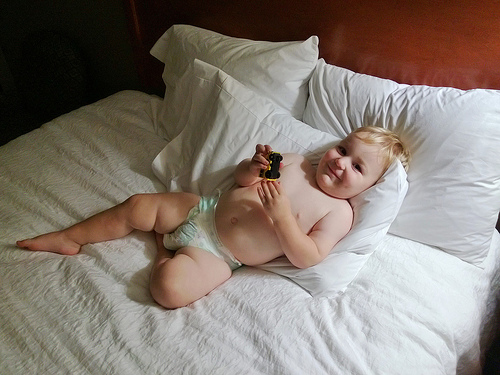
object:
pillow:
[302, 58, 500, 270]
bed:
[2, 88, 500, 374]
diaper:
[162, 197, 244, 271]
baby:
[17, 125, 412, 309]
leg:
[67, 191, 200, 246]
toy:
[259, 152, 282, 182]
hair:
[353, 125, 412, 176]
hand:
[256, 181, 293, 221]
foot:
[16, 231, 80, 254]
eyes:
[351, 162, 363, 176]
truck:
[257, 152, 284, 182]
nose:
[330, 156, 350, 170]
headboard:
[130, 0, 500, 98]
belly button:
[230, 217, 238, 226]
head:
[315, 125, 411, 199]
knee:
[126, 193, 146, 206]